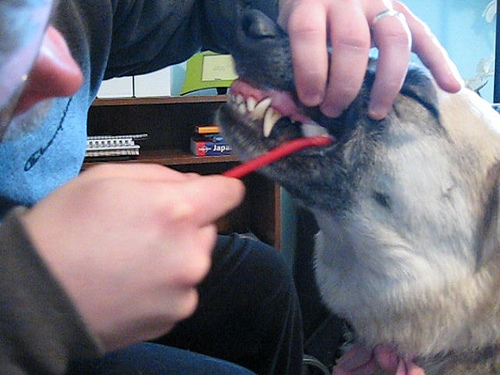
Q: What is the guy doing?
A: Brushing a dog's teeth.